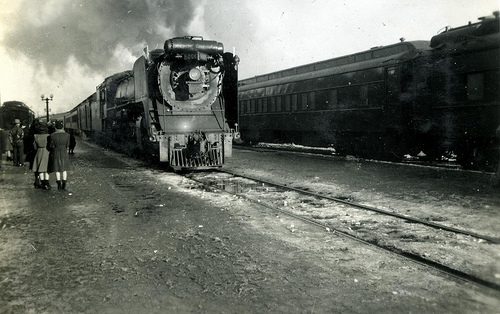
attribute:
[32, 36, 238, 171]
train — passing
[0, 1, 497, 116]
sky — above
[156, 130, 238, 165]
headlight — on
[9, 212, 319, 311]
ground — wet, muddy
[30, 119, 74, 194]
women — standing, waiting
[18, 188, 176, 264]
ground — with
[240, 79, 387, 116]
windows — closed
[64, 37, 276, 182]
train — on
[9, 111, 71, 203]
woman — elegantly-dressed, conservatively-dressed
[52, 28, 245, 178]
train — on, with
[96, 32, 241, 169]
engine — train, heavy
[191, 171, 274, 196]
puddle — on top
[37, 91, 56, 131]
pole — with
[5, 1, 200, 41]
steam — coming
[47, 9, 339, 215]
train — old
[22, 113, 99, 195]
women — wearing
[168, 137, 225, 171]
skirt — iron, train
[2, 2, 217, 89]
smoke — dark, coal, plumed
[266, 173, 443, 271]
track — below, by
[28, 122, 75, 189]
women — wearing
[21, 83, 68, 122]
lightpost — pictured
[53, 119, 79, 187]
persons — by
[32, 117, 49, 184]
persons — by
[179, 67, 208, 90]
light — by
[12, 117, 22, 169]
man — walking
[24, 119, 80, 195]
couple — upper-class, wealthy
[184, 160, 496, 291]
ground — muddy